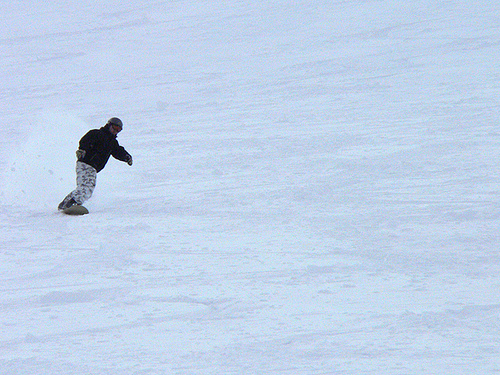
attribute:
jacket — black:
[75, 124, 126, 172]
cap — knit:
[103, 113, 120, 135]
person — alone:
[56, 115, 133, 209]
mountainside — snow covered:
[7, 8, 499, 373]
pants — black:
[76, 165, 100, 211]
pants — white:
[57, 161, 107, 206]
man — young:
[69, 116, 158, 173]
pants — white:
[68, 157, 95, 208]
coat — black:
[74, 127, 143, 167]